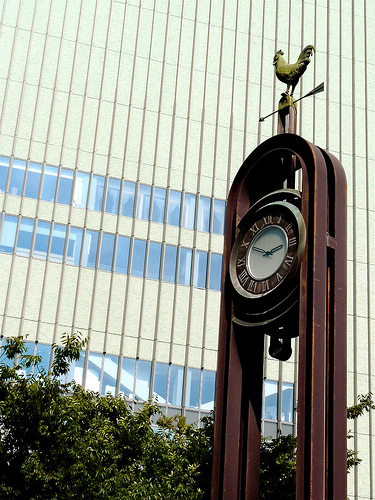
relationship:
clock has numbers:
[235, 220, 305, 295] [237, 253, 247, 282]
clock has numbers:
[235, 220, 305, 295] [255, 216, 289, 229]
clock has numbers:
[235, 220, 305, 295] [285, 231, 298, 267]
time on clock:
[250, 228, 285, 267] [231, 213, 301, 293]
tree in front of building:
[10, 388, 214, 493] [2, 10, 216, 448]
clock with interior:
[228, 199, 306, 299] [247, 249, 274, 274]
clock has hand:
[228, 199, 306, 299] [249, 243, 269, 256]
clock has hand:
[228, 199, 306, 299] [266, 241, 284, 259]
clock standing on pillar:
[228, 199, 306, 299] [295, 306, 346, 498]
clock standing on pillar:
[228, 199, 306, 299] [211, 320, 266, 498]